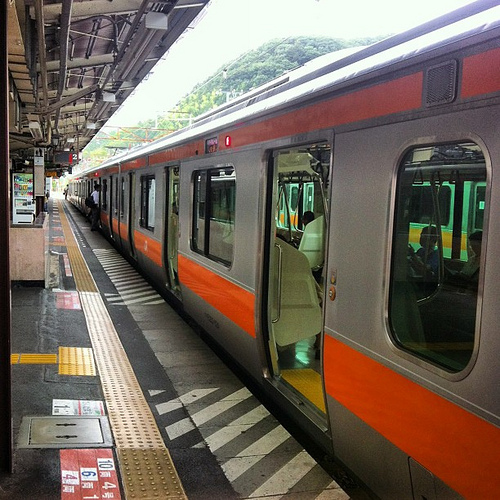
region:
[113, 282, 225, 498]
The ground is made of concrete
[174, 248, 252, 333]
The side of the train is orange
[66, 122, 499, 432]
The side of the bus is gray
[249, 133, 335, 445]
The door to the train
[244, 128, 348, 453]
The train door is open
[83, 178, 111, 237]
The man is getting on the train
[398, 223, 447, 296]
The man is sitting in the seat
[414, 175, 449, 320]
A holding bar in the train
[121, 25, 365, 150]
The trees are the color green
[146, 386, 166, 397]
white line on ground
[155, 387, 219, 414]
white line on ground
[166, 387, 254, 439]
white line on ground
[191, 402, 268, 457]
white line on ground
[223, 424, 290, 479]
white line on ground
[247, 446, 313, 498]
white line on ground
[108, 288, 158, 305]
white line on ground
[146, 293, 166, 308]
white line on ground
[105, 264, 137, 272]
white line on ground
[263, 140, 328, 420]
an open door on the side of the train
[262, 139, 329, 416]
an entrance way on the train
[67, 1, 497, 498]
a gray and orange transit train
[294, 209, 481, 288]
passengers on a train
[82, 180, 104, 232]
a man entering the train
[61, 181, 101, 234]
two people standing beside the train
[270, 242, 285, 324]
a metal handrail on the side of the entrance way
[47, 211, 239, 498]
a walkway for pedestrians in a train station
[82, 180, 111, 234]
a man in a white shirt getting on the train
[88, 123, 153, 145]
wires above the train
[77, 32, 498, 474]
a red and silver train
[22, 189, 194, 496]
the train platform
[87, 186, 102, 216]
a person getting on the train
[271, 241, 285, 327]
a handle on the train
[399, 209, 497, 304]
people sitting on the train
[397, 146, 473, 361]
a window on the train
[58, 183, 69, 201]
a person standing next to the train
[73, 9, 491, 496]
a train stopped at the station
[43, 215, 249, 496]
the boarding ramp at a train station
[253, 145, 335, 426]
the open door of a train car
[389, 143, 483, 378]
a passenger window on a train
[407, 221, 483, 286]
people seated inside a train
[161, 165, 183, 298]
the door of a train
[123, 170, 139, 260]
the door of a train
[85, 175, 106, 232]
a man stepping onto a train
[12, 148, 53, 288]
the ticket booth at a train station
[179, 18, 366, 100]
a woody mountainside